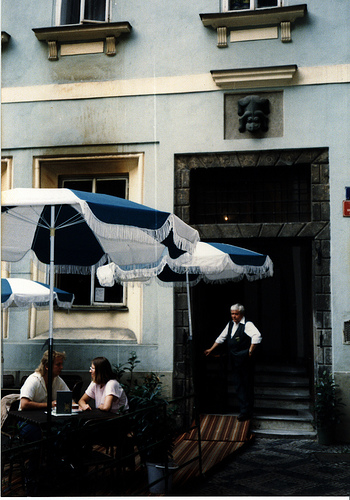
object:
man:
[204, 302, 262, 420]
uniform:
[214, 316, 261, 412]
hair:
[231, 303, 245, 319]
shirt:
[215, 316, 262, 345]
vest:
[236, 337, 241, 342]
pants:
[241, 367, 256, 416]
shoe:
[237, 412, 253, 421]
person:
[78, 355, 130, 410]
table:
[9, 408, 118, 429]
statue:
[236, 93, 272, 137]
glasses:
[89, 367, 95, 372]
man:
[17, 350, 78, 411]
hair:
[35, 350, 66, 374]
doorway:
[207, 242, 318, 437]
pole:
[46, 206, 55, 421]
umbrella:
[0, 187, 200, 276]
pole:
[185, 270, 204, 473]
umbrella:
[95, 240, 274, 287]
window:
[57, 172, 124, 307]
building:
[1, 0, 350, 438]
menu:
[56, 390, 73, 415]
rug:
[165, 408, 250, 469]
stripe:
[225, 417, 233, 441]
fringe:
[55, 270, 90, 275]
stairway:
[257, 334, 308, 415]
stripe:
[181, 441, 193, 460]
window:
[194, 175, 306, 221]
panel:
[166, 253, 228, 275]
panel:
[81, 200, 172, 242]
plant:
[315, 371, 341, 425]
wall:
[0, 55, 350, 161]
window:
[59, 0, 108, 23]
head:
[231, 310, 241, 324]